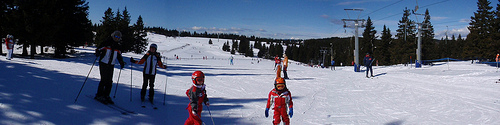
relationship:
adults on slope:
[90, 29, 130, 108] [151, 39, 302, 124]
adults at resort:
[90, 29, 130, 108] [2, 0, 497, 122]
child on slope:
[258, 77, 297, 125] [151, 39, 302, 124]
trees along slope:
[1, 0, 150, 58] [151, 39, 302, 124]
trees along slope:
[224, 0, 499, 66] [151, 39, 302, 124]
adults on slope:
[96, 29, 166, 103] [151, 39, 302, 124]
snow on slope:
[0, 31, 498, 124] [151, 39, 302, 124]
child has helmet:
[186, 70, 209, 124] [192, 68, 205, 84]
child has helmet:
[266, 77, 294, 124] [274, 77, 289, 86]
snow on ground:
[0, 31, 498, 124] [0, 33, 498, 124]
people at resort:
[92, 31, 378, 123] [2, 0, 497, 122]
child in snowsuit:
[186, 70, 209, 124] [182, 86, 209, 124]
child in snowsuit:
[266, 77, 294, 124] [269, 90, 293, 124]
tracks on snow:
[305, 105, 343, 124] [0, 31, 498, 124]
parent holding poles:
[126, 38, 175, 104] [128, 56, 171, 110]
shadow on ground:
[1, 63, 302, 124] [0, 33, 498, 124]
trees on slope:
[1, 0, 150, 58] [151, 39, 302, 124]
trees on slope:
[224, 0, 499, 66] [151, 39, 302, 124]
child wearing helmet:
[186, 70, 209, 124] [192, 68, 205, 84]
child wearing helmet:
[266, 77, 294, 124] [274, 77, 289, 86]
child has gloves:
[266, 77, 294, 124] [262, 107, 296, 117]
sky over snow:
[81, 1, 499, 40] [0, 31, 498, 124]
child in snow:
[186, 70, 209, 124] [0, 31, 498, 124]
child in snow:
[266, 77, 294, 124] [0, 31, 498, 124]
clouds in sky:
[329, 17, 474, 39] [81, 1, 499, 40]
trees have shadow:
[1, 0, 150, 58] [1, 63, 302, 124]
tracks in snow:
[305, 105, 343, 124] [0, 31, 498, 124]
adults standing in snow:
[90, 29, 130, 108] [0, 31, 498, 124]